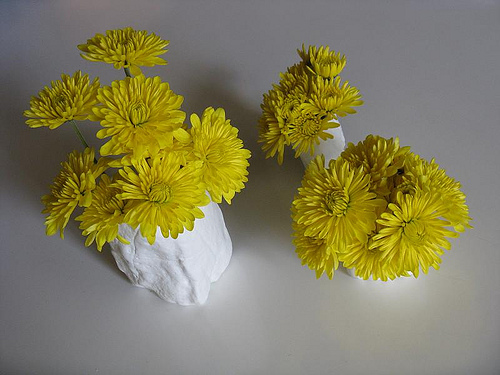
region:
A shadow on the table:
[198, 86, 310, 247]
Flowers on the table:
[264, 50, 466, 277]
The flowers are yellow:
[263, 51, 470, 283]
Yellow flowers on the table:
[1, 2, 498, 372]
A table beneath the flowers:
[1, 0, 497, 373]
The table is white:
[0, 0, 499, 373]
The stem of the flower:
[66, 120, 112, 176]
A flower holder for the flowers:
[108, 189, 234, 307]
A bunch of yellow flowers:
[23, 27, 471, 282]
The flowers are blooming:
[292, 138, 467, 282]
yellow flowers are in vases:
[27, 19, 471, 311]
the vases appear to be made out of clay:
[105, 112, 417, 315]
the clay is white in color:
[78, 200, 253, 305]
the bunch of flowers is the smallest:
[241, 36, 349, 161]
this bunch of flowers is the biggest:
[43, 26, 242, 317]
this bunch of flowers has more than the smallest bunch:
[278, 140, 469, 283]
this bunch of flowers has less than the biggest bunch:
[286, 132, 466, 282]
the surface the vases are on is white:
[33, 21, 464, 373]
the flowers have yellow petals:
[30, 25, 469, 281]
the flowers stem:
[68, 122, 97, 160]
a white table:
[14, 307, 489, 374]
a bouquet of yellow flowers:
[296, 135, 468, 277]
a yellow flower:
[26, 71, 99, 128]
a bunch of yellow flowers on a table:
[15, 31, 483, 316]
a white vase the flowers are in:
[111, 196, 233, 308]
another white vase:
[302, 124, 348, 173]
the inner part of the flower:
[149, 183, 174, 199]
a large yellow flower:
[97, 79, 179, 152]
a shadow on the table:
[238, 206, 298, 265]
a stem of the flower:
[73, 120, 85, 142]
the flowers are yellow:
[54, 43, 224, 234]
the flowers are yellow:
[307, 150, 439, 295]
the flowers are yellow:
[280, 66, 369, 147]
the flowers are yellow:
[259, 48, 321, 118]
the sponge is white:
[92, 195, 271, 330]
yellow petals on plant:
[125, 155, 243, 247]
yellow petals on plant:
[285, 175, 360, 221]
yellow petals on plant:
[360, 205, 475, 285]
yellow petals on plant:
[280, 106, 340, 141]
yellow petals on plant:
[115, 95, 165, 157]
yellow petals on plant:
[96, 80, 156, 160]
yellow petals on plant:
[60, 180, 115, 225]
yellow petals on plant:
[61, 80, 118, 131]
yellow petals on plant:
[125, 113, 176, 136]